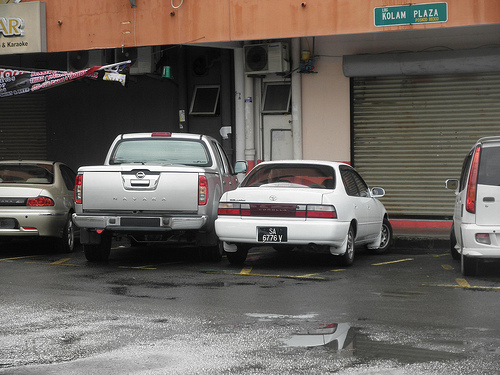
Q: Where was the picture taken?
A: It was taken at the parking lot.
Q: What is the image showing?
A: It is showing a parking lot.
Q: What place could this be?
A: It is a parking lot.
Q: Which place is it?
A: It is a parking lot.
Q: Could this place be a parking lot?
A: Yes, it is a parking lot.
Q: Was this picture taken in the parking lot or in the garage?
A: It was taken at the parking lot.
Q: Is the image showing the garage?
A: No, the picture is showing the parking lot.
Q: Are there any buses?
A: No, there are no buses.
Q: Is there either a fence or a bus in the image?
A: No, there are no buses or fences.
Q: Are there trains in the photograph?
A: No, there are no trains.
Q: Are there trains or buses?
A: No, there are no trains or buses.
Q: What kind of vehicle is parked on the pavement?
A: The vehicle is a car.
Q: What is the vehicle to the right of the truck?
A: The vehicle is a car.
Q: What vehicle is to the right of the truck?
A: The vehicle is a car.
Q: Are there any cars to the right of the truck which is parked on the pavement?
A: Yes, there is a car to the right of the truck.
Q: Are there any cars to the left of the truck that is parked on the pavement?
A: No, the car is to the right of the truck.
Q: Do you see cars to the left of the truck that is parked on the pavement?
A: No, the car is to the right of the truck.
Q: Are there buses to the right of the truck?
A: No, there is a car to the right of the truck.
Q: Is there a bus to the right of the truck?
A: No, there is a car to the right of the truck.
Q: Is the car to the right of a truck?
A: Yes, the car is to the right of a truck.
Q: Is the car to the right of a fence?
A: No, the car is to the right of a truck.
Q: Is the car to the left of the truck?
A: No, the car is to the right of the truck.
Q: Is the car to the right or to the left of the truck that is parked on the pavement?
A: The car is to the right of the truck.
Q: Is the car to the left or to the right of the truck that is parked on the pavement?
A: The car is to the right of the truck.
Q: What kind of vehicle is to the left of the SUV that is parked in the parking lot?
A: The vehicle is a car.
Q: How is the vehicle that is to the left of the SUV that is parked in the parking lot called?
A: The vehicle is a car.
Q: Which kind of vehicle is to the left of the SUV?
A: The vehicle is a car.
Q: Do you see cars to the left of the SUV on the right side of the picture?
A: Yes, there is a car to the left of the SUV.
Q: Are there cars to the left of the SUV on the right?
A: Yes, there is a car to the left of the SUV.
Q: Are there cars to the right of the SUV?
A: No, the car is to the left of the SUV.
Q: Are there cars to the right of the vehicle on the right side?
A: No, the car is to the left of the SUV.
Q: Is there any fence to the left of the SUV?
A: No, there is a car to the left of the SUV.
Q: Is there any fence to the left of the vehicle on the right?
A: No, there is a car to the left of the SUV.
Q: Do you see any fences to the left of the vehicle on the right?
A: No, there is a car to the left of the SUV.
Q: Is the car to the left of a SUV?
A: Yes, the car is to the left of a SUV.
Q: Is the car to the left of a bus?
A: No, the car is to the left of a SUV.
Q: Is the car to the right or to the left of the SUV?
A: The car is to the left of the SUV.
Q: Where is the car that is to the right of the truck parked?
A: The car is parked in the parking lot.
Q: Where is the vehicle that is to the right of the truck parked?
A: The car is parked in the parking lot.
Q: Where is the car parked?
A: The car is parked in the parking lot.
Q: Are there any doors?
A: Yes, there is a door.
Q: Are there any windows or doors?
A: Yes, there is a door.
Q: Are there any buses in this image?
A: No, there are no buses.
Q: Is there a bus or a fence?
A: No, there are no buses or fences.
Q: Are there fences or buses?
A: No, there are no buses or fences.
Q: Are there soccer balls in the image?
A: No, there are no soccer balls.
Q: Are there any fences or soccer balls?
A: No, there are no soccer balls or fences.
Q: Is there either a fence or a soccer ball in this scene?
A: No, there are no soccer balls or fences.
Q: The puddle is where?
A: The puddle is on the pavement.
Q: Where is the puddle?
A: The puddle is on the pavement.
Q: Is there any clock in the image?
A: No, there are no clocks.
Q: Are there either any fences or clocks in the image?
A: No, there are no clocks or fences.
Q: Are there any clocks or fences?
A: No, there are no clocks or fences.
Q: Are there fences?
A: No, there are no fences.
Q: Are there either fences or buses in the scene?
A: No, there are no fences or buses.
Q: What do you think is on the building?
A: The sign is on the building.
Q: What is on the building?
A: The sign is on the building.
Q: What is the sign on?
A: The sign is on the building.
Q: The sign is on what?
A: The sign is on the building.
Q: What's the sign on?
A: The sign is on the building.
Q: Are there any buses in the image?
A: No, there are no buses.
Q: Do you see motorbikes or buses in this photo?
A: No, there are no buses or motorbikes.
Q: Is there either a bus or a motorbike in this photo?
A: No, there are no buses or motorcycles.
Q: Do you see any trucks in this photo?
A: Yes, there is a truck.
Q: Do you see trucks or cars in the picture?
A: Yes, there is a truck.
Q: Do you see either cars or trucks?
A: Yes, there is a truck.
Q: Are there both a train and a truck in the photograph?
A: No, there is a truck but no trains.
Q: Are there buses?
A: No, there are no buses.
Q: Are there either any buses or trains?
A: No, there are no buses or trains.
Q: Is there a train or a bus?
A: No, there are no buses or trains.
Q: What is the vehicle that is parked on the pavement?
A: The vehicle is a truck.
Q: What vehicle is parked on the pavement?
A: The vehicle is a truck.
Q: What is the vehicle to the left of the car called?
A: The vehicle is a truck.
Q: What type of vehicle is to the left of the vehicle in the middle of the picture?
A: The vehicle is a truck.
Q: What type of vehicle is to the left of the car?
A: The vehicle is a truck.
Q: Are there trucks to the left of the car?
A: Yes, there is a truck to the left of the car.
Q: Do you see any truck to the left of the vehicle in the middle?
A: Yes, there is a truck to the left of the car.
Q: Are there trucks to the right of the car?
A: No, the truck is to the left of the car.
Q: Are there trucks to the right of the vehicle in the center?
A: No, the truck is to the left of the car.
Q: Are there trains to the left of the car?
A: No, there is a truck to the left of the car.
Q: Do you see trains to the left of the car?
A: No, there is a truck to the left of the car.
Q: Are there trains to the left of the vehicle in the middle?
A: No, there is a truck to the left of the car.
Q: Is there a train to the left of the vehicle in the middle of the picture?
A: No, there is a truck to the left of the car.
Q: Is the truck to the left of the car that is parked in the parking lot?
A: Yes, the truck is to the left of the car.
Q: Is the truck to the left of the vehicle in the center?
A: Yes, the truck is to the left of the car.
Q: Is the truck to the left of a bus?
A: No, the truck is to the left of the car.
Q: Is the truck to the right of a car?
A: No, the truck is to the left of a car.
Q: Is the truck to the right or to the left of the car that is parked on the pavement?
A: The truck is to the left of the car.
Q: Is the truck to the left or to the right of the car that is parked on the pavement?
A: The truck is to the left of the car.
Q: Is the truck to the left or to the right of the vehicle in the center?
A: The truck is to the left of the car.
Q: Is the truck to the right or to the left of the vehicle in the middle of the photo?
A: The truck is to the left of the car.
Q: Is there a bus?
A: No, there are no buses.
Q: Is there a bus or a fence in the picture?
A: No, there are no buses or fences.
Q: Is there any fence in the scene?
A: No, there are no fences.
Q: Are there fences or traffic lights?
A: No, there are no fences or traffic lights.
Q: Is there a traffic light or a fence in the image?
A: No, there are no fences or traffic lights.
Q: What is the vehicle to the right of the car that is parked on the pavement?
A: The vehicle is a SUV.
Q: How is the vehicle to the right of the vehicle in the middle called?
A: The vehicle is a SUV.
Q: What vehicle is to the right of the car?
A: The vehicle is a SUV.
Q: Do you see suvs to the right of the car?
A: Yes, there is a SUV to the right of the car.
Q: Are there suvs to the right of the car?
A: Yes, there is a SUV to the right of the car.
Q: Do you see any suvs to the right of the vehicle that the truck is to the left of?
A: Yes, there is a SUV to the right of the car.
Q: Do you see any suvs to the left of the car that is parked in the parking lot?
A: No, the SUV is to the right of the car.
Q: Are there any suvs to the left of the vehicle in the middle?
A: No, the SUV is to the right of the car.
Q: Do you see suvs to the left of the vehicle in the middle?
A: No, the SUV is to the right of the car.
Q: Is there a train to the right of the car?
A: No, there is a SUV to the right of the car.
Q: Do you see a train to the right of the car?
A: No, there is a SUV to the right of the car.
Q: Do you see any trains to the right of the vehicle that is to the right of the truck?
A: No, there is a SUV to the right of the car.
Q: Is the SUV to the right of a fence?
A: No, the SUV is to the right of a car.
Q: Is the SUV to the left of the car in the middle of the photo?
A: No, the SUV is to the right of the car.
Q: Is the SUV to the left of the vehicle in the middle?
A: No, the SUV is to the right of the car.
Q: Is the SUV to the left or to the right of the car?
A: The SUV is to the right of the car.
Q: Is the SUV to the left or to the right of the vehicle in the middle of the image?
A: The SUV is to the right of the car.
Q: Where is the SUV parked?
A: The SUV is parked in the parking lot.